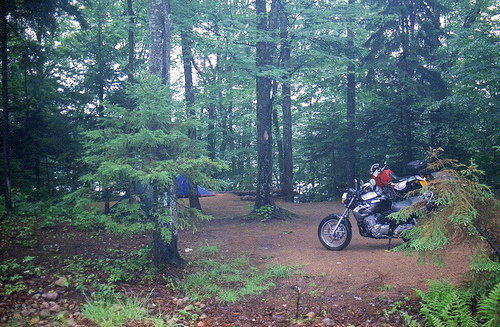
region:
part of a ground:
[261, 245, 298, 296]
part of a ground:
[236, 213, 256, 245]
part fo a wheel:
[315, 204, 342, 239]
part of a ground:
[289, 228, 317, 275]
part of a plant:
[404, 165, 452, 289]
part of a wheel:
[307, 197, 349, 279]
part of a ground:
[254, 208, 293, 277]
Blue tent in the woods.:
[130, 170, 214, 204]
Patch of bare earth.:
[205, 225, 302, 253]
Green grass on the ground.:
[176, 258, 293, 307]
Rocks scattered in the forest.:
[13, 277, 69, 324]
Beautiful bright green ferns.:
[398, 277, 491, 325]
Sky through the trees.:
[49, 24, 222, 102]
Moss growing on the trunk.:
[254, 154, 274, 206]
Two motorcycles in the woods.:
[297, 147, 439, 252]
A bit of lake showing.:
[254, 172, 323, 200]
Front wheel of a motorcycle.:
[301, 207, 356, 257]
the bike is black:
[336, 172, 441, 251]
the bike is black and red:
[362, 158, 442, 203]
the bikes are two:
[321, 148, 449, 239]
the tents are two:
[119, 155, 209, 237]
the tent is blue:
[163, 169, 228, 204]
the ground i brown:
[241, 213, 321, 293]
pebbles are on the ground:
[43, 265, 197, 325]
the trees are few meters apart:
[16, 35, 478, 150]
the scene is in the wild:
[4, 10, 473, 320]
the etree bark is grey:
[244, 13, 274, 206]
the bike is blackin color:
[324, 190, 455, 272]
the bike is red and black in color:
[368, 155, 439, 190]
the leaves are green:
[1, 18, 498, 189]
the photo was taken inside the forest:
[7, 7, 498, 325]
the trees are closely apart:
[14, 9, 490, 244]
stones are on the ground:
[21, 270, 409, 325]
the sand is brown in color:
[238, 216, 343, 287]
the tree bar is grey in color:
[248, 107, 278, 194]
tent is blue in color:
[176, 174, 247, 207]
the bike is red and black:
[370, 150, 425, 185]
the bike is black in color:
[318, 186, 450, 256]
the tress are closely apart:
[2, 0, 494, 282]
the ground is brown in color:
[263, 210, 321, 262]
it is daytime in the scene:
[4, 2, 499, 322]